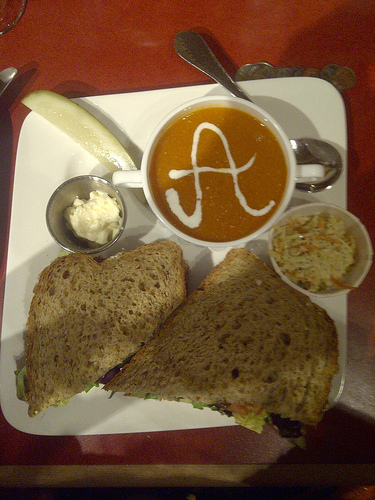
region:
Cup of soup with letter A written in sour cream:
[111, 91, 296, 244]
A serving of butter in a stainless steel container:
[37, 167, 146, 268]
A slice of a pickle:
[16, 87, 142, 191]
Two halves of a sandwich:
[6, 234, 349, 453]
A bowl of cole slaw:
[267, 203, 372, 299]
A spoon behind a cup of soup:
[167, 22, 373, 197]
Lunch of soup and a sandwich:
[6, 12, 370, 486]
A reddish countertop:
[54, 16, 156, 71]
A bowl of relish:
[257, 188, 372, 303]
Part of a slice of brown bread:
[53, 277, 138, 340]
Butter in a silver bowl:
[41, 172, 126, 252]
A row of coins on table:
[236, 59, 359, 87]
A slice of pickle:
[17, 92, 135, 171]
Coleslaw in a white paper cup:
[268, 202, 374, 294]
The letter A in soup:
[148, 102, 294, 242]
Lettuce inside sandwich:
[216, 401, 302, 441]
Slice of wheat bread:
[30, 254, 105, 401]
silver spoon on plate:
[290, 134, 341, 192]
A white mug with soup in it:
[115, 94, 299, 243]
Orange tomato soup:
[240, 135, 278, 176]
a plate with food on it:
[9, 75, 354, 431]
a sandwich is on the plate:
[17, 247, 348, 445]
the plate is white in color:
[1, 72, 338, 434]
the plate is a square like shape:
[8, 73, 353, 441]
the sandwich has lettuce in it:
[240, 410, 307, 443]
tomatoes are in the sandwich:
[225, 397, 264, 413]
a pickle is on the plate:
[18, 89, 148, 205]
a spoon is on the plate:
[174, 28, 345, 196]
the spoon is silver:
[174, 30, 341, 196]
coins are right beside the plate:
[233, 55, 359, 90]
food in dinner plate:
[0, 17, 365, 476]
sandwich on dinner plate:
[6, 231, 369, 466]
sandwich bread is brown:
[8, 238, 350, 450]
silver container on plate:
[34, 165, 134, 261]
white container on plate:
[239, 165, 371, 320]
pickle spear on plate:
[22, 66, 154, 212]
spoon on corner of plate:
[165, 19, 361, 219]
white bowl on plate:
[133, 82, 304, 264]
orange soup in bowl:
[133, 100, 301, 254]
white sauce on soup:
[128, 73, 290, 254]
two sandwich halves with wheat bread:
[15, 232, 346, 459]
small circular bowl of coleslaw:
[267, 196, 373, 301]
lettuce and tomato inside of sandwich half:
[150, 393, 318, 453]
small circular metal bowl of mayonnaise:
[37, 169, 129, 255]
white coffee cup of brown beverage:
[106, 97, 299, 255]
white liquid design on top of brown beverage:
[158, 120, 282, 232]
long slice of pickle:
[18, 88, 152, 208]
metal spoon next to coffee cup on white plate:
[161, 30, 354, 196]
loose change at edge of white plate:
[230, 56, 361, 92]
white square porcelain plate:
[2, 70, 373, 445]